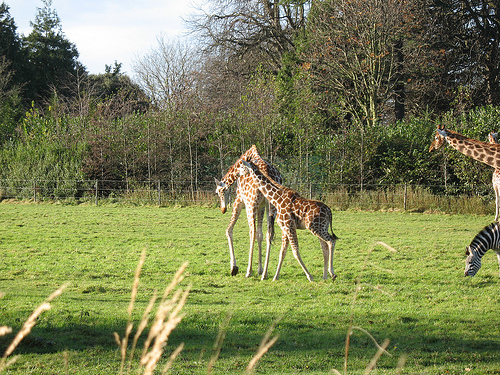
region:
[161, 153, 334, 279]
two giraffes in field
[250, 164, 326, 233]
spots are on anmial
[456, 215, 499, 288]
black and white stripes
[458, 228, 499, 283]
animal eating the grass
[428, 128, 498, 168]
long neck of giraffe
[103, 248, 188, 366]
tall weeds in the grass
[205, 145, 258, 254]
animal looking down at ground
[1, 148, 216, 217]
fence surrounding the area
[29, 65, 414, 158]
trees behind the fence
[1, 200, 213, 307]
grass is short and green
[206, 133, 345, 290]
a baby giraffe and its mother are together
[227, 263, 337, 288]
the giraffes have white and black hooves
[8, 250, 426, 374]
brown grass is growing in the field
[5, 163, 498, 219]
a fence surrounds the field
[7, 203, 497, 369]
the field has cut green grass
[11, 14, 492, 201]
trees are behind the enclosure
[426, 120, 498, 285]
giraffes and a zebra are together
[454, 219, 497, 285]
the zebra is grazing on grass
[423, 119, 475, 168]
the giraffe has black marking on its head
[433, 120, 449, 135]
the giraffe's horns are brown and black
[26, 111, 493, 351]
giraffes and zebra on green grass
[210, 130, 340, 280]
adult giraffe next to young giraffe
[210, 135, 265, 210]
sharp angle created with bent neck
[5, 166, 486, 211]
fencing along edge of grass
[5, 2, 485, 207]
trees in back of fencing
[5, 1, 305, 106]
blue sky with clouds above trees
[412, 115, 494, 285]
zebra and giraffe heads sticking out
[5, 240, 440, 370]
heads of golden grasses pointing upwards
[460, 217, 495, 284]
zebra bending to graze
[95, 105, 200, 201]
trees with slender trunks in a row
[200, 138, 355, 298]
two giraffes in a field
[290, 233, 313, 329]
leg of a giraffe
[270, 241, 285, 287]
leg of a giraffe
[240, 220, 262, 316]
leg of a giraffe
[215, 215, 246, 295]
leg of a giraffe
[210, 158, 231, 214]
face of a giraffe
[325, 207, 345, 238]
tail of a giraffe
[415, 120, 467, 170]
head of a giraffe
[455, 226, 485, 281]
black and white zebra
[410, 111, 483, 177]
brown zebra in a field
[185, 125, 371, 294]
Two animals in the center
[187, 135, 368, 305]
The animals are brown and yellow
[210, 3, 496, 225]
Trees are in the background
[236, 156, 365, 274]
This is a baby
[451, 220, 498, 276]
Zebra in the corner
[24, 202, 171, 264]
Grass is short green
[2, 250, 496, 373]
Plants in the front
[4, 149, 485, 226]
A gate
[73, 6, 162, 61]
Clouds in the sky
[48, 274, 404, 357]
Shadow on the ground